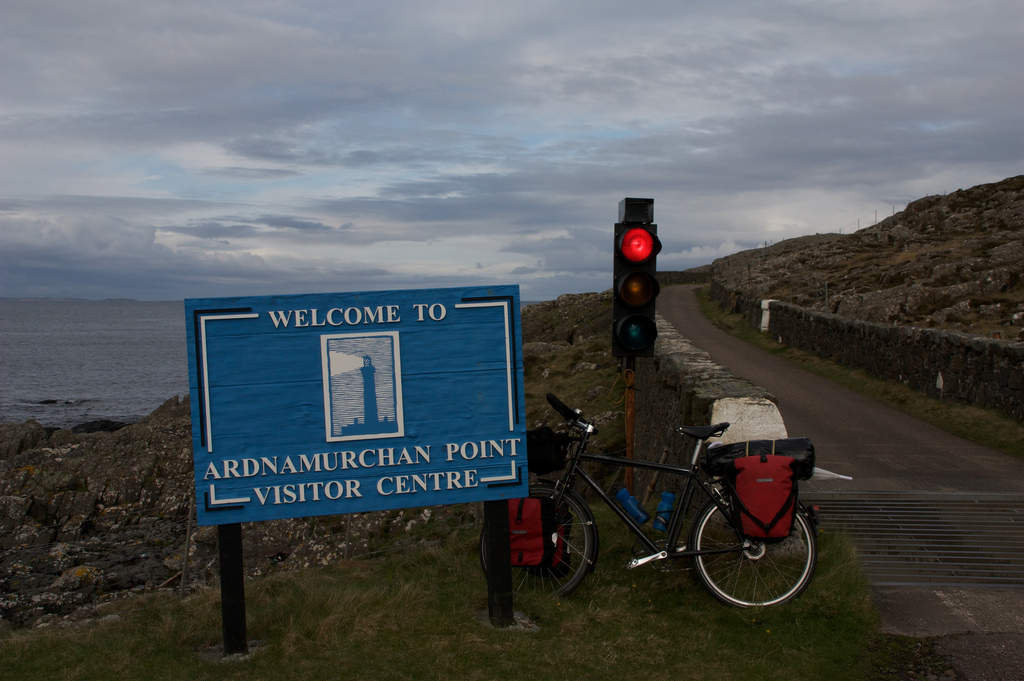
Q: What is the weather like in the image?
A: It is cloudy.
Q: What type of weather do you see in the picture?
A: It is cloudy.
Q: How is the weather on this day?
A: It is cloudy.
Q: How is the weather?
A: It is cloudy.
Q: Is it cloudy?
A: Yes, it is cloudy.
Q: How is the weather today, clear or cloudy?
A: It is cloudy.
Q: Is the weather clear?
A: No, it is cloudy.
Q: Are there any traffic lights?
A: Yes, there is a traffic light.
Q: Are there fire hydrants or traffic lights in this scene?
A: Yes, there is a traffic light.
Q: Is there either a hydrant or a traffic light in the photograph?
A: Yes, there is a traffic light.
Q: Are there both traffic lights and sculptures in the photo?
A: No, there is a traffic light but no sculptures.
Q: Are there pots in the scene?
A: No, there are no pots.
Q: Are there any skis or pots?
A: No, there are no pots or skis.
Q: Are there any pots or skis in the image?
A: No, there are no pots or skis.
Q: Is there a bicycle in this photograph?
A: Yes, there is a bicycle.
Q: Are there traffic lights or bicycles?
A: Yes, there is a bicycle.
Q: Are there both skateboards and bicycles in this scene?
A: No, there is a bicycle but no skateboards.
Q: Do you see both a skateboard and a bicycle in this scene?
A: No, there is a bicycle but no skateboards.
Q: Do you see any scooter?
A: No, there are no scooters.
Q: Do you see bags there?
A: Yes, there is a bag.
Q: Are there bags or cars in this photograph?
A: Yes, there is a bag.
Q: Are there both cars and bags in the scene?
A: No, there is a bag but no cars.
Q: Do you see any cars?
A: No, there are no cars.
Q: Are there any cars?
A: No, there are no cars.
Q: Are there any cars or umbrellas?
A: No, there are no cars or umbrellas.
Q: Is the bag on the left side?
A: No, the bag is on the right of the image.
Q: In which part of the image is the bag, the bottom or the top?
A: The bag is in the bottom of the image.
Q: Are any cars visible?
A: No, there are no cars.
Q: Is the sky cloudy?
A: Yes, the sky is cloudy.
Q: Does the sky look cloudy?
A: Yes, the sky is cloudy.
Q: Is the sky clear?
A: No, the sky is cloudy.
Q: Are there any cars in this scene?
A: No, there are no cars.